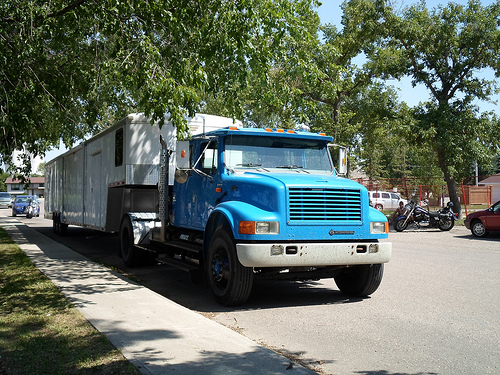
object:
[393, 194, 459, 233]
motorcycle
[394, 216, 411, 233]
two wheels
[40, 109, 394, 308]
truck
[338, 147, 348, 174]
side mirror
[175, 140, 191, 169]
side mirror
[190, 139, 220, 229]
passenger door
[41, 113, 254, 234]
trailer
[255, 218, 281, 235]
headlights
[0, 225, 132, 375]
grass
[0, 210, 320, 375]
sidewalk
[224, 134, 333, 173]
windscreen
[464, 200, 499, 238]
car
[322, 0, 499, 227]
tree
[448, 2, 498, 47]
leaves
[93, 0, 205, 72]
leaves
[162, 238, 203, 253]
steps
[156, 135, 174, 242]
smokestack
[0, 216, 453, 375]
shadow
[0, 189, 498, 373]
street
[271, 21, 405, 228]
tree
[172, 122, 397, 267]
truck cab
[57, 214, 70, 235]
tires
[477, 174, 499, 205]
house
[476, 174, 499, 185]
roof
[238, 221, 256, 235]
turn signals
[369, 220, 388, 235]
signal lights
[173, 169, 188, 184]
attached mirror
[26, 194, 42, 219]
motorcycle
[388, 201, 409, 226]
man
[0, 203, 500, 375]
ground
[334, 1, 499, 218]
trees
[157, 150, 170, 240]
exhaust pipe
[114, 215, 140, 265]
tire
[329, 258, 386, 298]
tire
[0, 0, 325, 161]
trees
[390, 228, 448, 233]
shadow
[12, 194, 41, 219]
car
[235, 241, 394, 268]
bumper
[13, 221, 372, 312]
shadow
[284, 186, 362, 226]
grille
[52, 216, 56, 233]
back wheels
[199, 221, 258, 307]
four wheels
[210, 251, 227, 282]
hubcap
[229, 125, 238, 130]
clearance lights